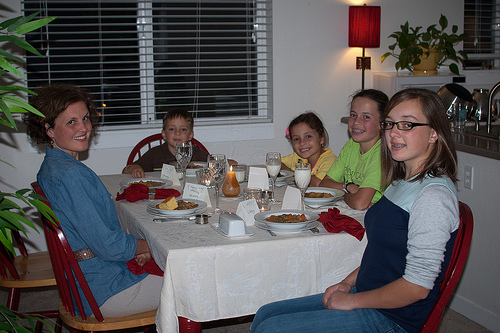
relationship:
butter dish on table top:
[212, 210, 248, 243] [99, 165, 365, 250]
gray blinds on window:
[20, 2, 272, 124] [16, 0, 276, 132]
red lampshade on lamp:
[349, 5, 381, 47] [347, 5, 382, 87]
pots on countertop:
[442, 73, 496, 117] [453, 127, 496, 164]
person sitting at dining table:
[22, 80, 163, 317] [97, 162, 376, 332]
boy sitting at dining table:
[121, 107, 239, 178] [97, 162, 376, 332]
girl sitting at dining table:
[280, 111, 338, 187] [97, 162, 376, 332]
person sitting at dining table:
[319, 88, 389, 208] [97, 162, 376, 332]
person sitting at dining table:
[247, 83, 461, 329] [97, 162, 376, 332]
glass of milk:
[291, 160, 314, 186] [298, 177, 308, 189]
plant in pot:
[387, 9, 469, 76] [409, 49, 439, 73]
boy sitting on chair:
[123, 107, 227, 178] [127, 131, 212, 166]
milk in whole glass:
[290, 167, 310, 190] [292, 160, 311, 210]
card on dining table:
[238, 200, 269, 222] [97, 162, 376, 332]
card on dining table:
[245, 159, 273, 187] [97, 162, 376, 332]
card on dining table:
[157, 159, 179, 178] [97, 162, 376, 332]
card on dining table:
[183, 174, 209, 204] [97, 162, 376, 332]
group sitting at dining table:
[22, 79, 462, 331] [97, 162, 376, 332]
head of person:
[378, 87, 448, 162] [247, 83, 461, 329]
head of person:
[26, 78, 101, 165] [20, 80, 183, 317]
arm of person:
[322, 192, 454, 316] [247, 83, 461, 329]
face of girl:
[287, 120, 317, 158] [277, 111, 338, 184]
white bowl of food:
[246, 206, 322, 236] [263, 213, 312, 225]